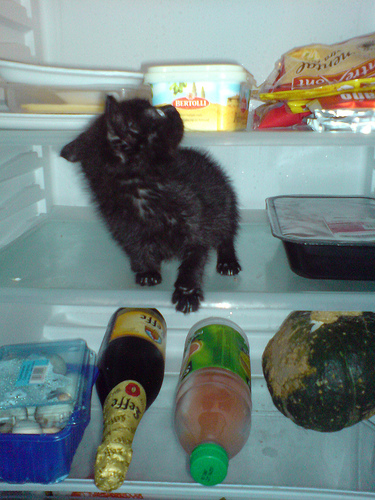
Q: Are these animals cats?
A: No, there are both cats and lobsters.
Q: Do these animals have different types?
A: Yes, they are cats and lobsters.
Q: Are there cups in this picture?
A: No, there are no cups.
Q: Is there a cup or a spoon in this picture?
A: No, there are no cups or spoons.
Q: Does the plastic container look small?
A: Yes, the container is small.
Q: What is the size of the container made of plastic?
A: The container is small.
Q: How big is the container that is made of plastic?
A: The container is small.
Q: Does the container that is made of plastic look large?
A: No, the container is small.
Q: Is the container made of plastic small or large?
A: The container is small.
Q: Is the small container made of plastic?
A: Yes, the container is made of plastic.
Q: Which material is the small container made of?
A: The container is made of plastic.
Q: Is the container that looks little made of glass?
A: No, the container is made of plastic.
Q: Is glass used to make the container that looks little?
A: No, the container is made of plastic.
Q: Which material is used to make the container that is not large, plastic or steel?
A: The container is made of plastic.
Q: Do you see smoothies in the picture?
A: No, there are no smoothies.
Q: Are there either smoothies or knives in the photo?
A: No, there are no smoothies or knives.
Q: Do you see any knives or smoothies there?
A: No, there are no smoothies or knives.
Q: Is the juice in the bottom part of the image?
A: Yes, the juice is in the bottom of the image.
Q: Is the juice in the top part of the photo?
A: No, the juice is in the bottom of the image.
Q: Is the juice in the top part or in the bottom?
A: The juice is in the bottom of the image.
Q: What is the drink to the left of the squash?
A: The drink is juice.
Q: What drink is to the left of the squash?
A: The drink is juice.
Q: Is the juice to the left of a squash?
A: Yes, the juice is to the left of a squash.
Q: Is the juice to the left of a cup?
A: No, the juice is to the left of a squash.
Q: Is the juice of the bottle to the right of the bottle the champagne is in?
A: Yes, the juice is to the right of the bottle.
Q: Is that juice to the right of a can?
A: No, the juice is to the right of the bottle.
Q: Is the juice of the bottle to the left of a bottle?
A: No, the juice is to the right of a bottle.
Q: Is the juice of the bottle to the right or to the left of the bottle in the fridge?
A: The juice is to the right of the bottle.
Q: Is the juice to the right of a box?
A: Yes, the juice is to the right of a box.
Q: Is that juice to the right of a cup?
A: No, the juice is to the right of a box.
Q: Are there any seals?
A: Yes, there is a seal.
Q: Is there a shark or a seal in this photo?
A: Yes, there is a seal.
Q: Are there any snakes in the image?
A: No, there are no snakes.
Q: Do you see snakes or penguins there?
A: No, there are no snakes or penguins.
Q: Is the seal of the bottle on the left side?
A: Yes, the seal is on the left of the image.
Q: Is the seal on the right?
A: No, the seal is on the left of the image.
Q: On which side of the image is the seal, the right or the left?
A: The seal is on the left of the image.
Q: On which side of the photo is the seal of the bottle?
A: The seal is on the left of the image.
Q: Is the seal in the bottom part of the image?
A: Yes, the seal is in the bottom of the image.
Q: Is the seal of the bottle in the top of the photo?
A: No, the seal is in the bottom of the image.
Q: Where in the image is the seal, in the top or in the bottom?
A: The seal is in the bottom of the image.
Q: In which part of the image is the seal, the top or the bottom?
A: The seal is in the bottom of the image.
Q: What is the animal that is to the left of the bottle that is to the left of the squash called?
A: The animal is a seal.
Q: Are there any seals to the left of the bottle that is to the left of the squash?
A: Yes, there is a seal to the left of the bottle.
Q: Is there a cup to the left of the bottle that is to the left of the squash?
A: No, there is a seal to the left of the bottle.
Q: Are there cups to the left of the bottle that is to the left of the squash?
A: No, there is a seal to the left of the bottle.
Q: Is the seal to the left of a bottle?
A: Yes, the seal is to the left of a bottle.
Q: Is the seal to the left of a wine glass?
A: No, the seal is to the left of a bottle.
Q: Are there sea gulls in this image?
A: No, there are no sea gulls.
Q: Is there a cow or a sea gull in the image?
A: No, there are no seagulls or cows.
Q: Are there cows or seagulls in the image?
A: No, there are no seagulls or cows.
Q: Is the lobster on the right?
A: Yes, the lobster is on the right of the image.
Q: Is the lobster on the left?
A: No, the lobster is on the right of the image.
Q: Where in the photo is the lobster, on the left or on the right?
A: The lobster is on the right of the image.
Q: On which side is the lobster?
A: The lobster is on the right of the image.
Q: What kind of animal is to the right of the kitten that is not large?
A: The animal is a lobster.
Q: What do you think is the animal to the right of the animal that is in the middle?
A: The animal is a lobster.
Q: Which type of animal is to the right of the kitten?
A: The animal is a lobster.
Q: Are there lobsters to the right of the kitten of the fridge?
A: Yes, there is a lobster to the right of the kitten.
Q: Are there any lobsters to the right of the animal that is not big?
A: Yes, there is a lobster to the right of the kitten.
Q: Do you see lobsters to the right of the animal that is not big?
A: Yes, there is a lobster to the right of the kitten.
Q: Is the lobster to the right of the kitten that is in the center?
A: Yes, the lobster is to the right of the kitten.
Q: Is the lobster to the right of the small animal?
A: Yes, the lobster is to the right of the kitten.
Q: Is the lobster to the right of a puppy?
A: No, the lobster is to the right of the kitten.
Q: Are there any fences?
A: No, there are no fences.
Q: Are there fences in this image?
A: No, there are no fences.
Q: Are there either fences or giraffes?
A: No, there are no fences or giraffes.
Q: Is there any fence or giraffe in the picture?
A: No, there are no fences or giraffes.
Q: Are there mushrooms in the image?
A: Yes, there are mushrooms.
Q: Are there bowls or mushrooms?
A: Yes, there are mushrooms.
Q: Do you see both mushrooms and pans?
A: No, there are mushrooms but no pans.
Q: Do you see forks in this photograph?
A: No, there are no forks.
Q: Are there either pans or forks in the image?
A: No, there are no forks or pans.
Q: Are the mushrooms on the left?
A: Yes, the mushrooms are on the left of the image.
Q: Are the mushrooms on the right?
A: No, the mushrooms are on the left of the image.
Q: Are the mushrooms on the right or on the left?
A: The mushrooms are on the left of the image.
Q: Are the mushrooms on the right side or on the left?
A: The mushrooms are on the left of the image.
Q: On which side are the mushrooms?
A: The mushrooms are on the left of the image.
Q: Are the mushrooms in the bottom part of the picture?
A: Yes, the mushrooms are in the bottom of the image.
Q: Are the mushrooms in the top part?
A: No, the mushrooms are in the bottom of the image.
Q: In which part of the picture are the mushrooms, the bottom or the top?
A: The mushrooms are in the bottom of the image.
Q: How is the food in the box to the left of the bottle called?
A: The food is mushrooms.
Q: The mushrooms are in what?
A: The mushrooms are in the box.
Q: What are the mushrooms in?
A: The mushrooms are in the box.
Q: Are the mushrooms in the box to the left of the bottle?
A: Yes, the mushrooms are in the box.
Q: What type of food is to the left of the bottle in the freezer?
A: The food is mushrooms.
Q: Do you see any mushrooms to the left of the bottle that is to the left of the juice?
A: Yes, there are mushrooms to the left of the bottle.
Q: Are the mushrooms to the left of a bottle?
A: Yes, the mushrooms are to the left of a bottle.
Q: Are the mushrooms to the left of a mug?
A: No, the mushrooms are to the left of a bottle.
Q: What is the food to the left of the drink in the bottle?
A: The food is mushrooms.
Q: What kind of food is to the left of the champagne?
A: The food is mushrooms.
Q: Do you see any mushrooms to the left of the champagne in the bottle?
A: Yes, there are mushrooms to the left of the champagne.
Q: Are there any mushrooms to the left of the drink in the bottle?
A: Yes, there are mushrooms to the left of the champagne.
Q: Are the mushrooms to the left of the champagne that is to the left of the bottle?
A: Yes, the mushrooms are to the left of the champagne.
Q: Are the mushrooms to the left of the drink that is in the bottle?
A: Yes, the mushrooms are to the left of the champagne.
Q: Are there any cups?
A: No, there are no cups.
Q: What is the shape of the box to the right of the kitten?
A: The box is square.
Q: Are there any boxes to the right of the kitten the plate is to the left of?
A: Yes, there is a box to the right of the kitten.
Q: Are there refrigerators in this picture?
A: Yes, there is a refrigerator.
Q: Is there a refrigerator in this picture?
A: Yes, there is a refrigerator.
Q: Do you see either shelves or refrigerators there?
A: Yes, there is a refrigerator.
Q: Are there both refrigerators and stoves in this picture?
A: No, there is a refrigerator but no stoves.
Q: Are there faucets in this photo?
A: No, there are no faucets.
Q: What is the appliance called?
A: The appliance is a refrigerator.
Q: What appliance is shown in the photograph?
A: The appliance is a refrigerator.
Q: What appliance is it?
A: The appliance is a refrigerator.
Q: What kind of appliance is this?
A: This is a refrigerator.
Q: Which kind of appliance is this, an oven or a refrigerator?
A: This is a refrigerator.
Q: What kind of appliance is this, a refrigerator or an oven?
A: This is a refrigerator.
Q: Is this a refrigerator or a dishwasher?
A: This is a refrigerator.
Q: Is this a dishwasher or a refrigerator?
A: This is a refrigerator.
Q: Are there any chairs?
A: No, there are no chairs.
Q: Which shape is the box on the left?
A: The box is square.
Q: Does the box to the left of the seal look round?
A: No, the box is square.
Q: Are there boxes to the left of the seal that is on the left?
A: Yes, there is a box to the left of the seal.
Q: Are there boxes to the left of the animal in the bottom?
A: Yes, there is a box to the left of the seal.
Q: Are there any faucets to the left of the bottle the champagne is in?
A: No, there is a box to the left of the bottle.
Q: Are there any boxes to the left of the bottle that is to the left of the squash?
A: Yes, there is a box to the left of the bottle.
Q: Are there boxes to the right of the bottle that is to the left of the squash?
A: No, the box is to the left of the bottle.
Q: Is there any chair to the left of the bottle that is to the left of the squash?
A: No, there is a box to the left of the bottle.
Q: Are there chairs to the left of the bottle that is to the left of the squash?
A: No, there is a box to the left of the bottle.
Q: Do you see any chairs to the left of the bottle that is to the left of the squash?
A: No, there is a box to the left of the bottle.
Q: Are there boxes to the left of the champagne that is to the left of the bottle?
A: Yes, there is a box to the left of the champagne.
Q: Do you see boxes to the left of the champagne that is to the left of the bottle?
A: Yes, there is a box to the left of the champagne.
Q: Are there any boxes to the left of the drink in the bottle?
A: Yes, there is a box to the left of the champagne.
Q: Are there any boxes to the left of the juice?
A: Yes, there is a box to the left of the juice.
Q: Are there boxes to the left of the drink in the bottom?
A: Yes, there is a box to the left of the juice.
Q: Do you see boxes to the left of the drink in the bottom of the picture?
A: Yes, there is a box to the left of the juice.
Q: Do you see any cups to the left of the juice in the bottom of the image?
A: No, there is a box to the left of the juice.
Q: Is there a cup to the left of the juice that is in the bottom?
A: No, there is a box to the left of the juice.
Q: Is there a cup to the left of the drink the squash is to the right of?
A: No, there is a box to the left of the juice.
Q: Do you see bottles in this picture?
A: Yes, there is a bottle.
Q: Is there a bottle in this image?
A: Yes, there is a bottle.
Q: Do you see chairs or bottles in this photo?
A: Yes, there is a bottle.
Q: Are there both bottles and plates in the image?
A: Yes, there are both a bottle and a plate.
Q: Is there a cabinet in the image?
A: No, there are no cabinets.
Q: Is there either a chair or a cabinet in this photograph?
A: No, there are no cabinets or chairs.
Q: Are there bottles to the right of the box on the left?
A: Yes, there is a bottle to the right of the box.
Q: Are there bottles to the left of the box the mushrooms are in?
A: No, the bottle is to the right of the box.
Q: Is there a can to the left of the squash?
A: No, there is a bottle to the left of the squash.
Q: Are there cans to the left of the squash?
A: No, there is a bottle to the left of the squash.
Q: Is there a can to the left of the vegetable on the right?
A: No, there is a bottle to the left of the squash.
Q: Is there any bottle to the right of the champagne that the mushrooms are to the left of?
A: Yes, there is a bottle to the right of the champagne.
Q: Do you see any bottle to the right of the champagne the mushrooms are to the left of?
A: Yes, there is a bottle to the right of the champagne.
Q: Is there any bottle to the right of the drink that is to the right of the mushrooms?
A: Yes, there is a bottle to the right of the champagne.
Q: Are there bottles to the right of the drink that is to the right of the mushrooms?
A: Yes, there is a bottle to the right of the champagne.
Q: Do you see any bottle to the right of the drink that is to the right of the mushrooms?
A: Yes, there is a bottle to the right of the champagne.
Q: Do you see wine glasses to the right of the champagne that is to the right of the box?
A: No, there is a bottle to the right of the champagne.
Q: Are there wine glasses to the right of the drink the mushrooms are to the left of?
A: No, there is a bottle to the right of the champagne.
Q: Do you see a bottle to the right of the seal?
A: Yes, there is a bottle to the right of the seal.